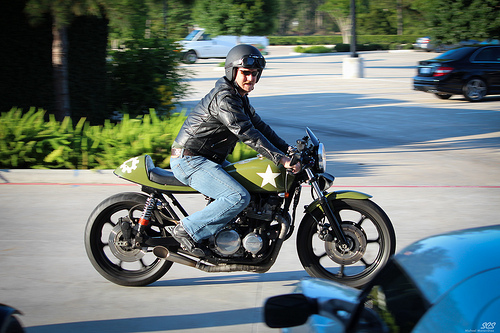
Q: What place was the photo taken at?
A: It was taken at the parking lot.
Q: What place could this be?
A: It is a parking lot.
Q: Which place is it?
A: It is a parking lot.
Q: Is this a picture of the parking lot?
A: Yes, it is showing the parking lot.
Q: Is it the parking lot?
A: Yes, it is the parking lot.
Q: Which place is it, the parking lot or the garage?
A: It is the parking lot.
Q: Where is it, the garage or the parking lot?
A: It is the parking lot.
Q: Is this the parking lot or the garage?
A: It is the parking lot.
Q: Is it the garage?
A: No, it is the parking lot.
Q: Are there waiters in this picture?
A: No, there are no waiters.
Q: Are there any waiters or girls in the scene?
A: No, there are no waiters or girls.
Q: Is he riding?
A: Yes, the man is riding.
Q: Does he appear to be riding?
A: Yes, the man is riding.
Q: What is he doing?
A: The man is riding.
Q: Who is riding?
A: The man is riding.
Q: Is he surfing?
A: No, the man is riding.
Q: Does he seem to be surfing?
A: No, the man is riding.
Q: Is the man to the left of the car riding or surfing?
A: The man is riding.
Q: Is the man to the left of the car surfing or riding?
A: The man is riding.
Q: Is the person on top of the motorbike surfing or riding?
A: The man is riding.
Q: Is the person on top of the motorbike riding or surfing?
A: The man is riding.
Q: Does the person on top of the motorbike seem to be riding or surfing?
A: The man is riding.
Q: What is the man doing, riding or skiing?
A: The man is riding.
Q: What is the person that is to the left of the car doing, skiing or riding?
A: The man is riding.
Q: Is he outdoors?
A: Yes, the man is outdoors.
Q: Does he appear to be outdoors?
A: Yes, the man is outdoors.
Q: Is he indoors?
A: No, the man is outdoors.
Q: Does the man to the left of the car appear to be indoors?
A: No, the man is outdoors.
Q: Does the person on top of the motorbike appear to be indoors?
A: No, the man is outdoors.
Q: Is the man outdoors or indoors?
A: The man is outdoors.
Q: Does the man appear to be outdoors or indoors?
A: The man is outdoors.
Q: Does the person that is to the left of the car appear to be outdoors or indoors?
A: The man is outdoors.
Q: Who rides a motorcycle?
A: The man rides a motorcycle.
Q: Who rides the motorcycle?
A: The man rides a motorcycle.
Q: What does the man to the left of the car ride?
A: The man rides a motorcycle.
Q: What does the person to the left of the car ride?
A: The man rides a motorcycle.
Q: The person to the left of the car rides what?
A: The man rides a motorcycle.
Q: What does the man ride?
A: The man rides a motorcycle.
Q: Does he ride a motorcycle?
A: Yes, the man rides a motorcycle.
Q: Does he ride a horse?
A: No, the man rides a motorcycle.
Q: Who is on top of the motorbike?
A: The man is on top of the motorbike.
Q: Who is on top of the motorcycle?
A: The man is on top of the motorbike.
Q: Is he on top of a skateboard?
A: No, the man is on top of the motorcycle.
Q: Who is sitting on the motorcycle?
A: The man is sitting on the motorcycle.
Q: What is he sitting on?
A: The man is sitting on the motorbike.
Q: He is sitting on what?
A: The man is sitting on the motorbike.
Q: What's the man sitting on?
A: The man is sitting on the motorbike.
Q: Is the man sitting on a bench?
A: No, the man is sitting on the motorbike.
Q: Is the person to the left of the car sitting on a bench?
A: No, the man is sitting on the motorbike.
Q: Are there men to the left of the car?
A: Yes, there is a man to the left of the car.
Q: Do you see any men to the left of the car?
A: Yes, there is a man to the left of the car.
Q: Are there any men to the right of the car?
A: No, the man is to the left of the car.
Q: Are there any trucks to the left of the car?
A: No, there is a man to the left of the car.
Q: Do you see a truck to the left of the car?
A: No, there is a man to the left of the car.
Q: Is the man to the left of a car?
A: Yes, the man is to the left of a car.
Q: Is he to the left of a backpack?
A: No, the man is to the left of a car.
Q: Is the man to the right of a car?
A: No, the man is to the left of a car.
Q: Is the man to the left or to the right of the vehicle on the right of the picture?
A: The man is to the left of the car.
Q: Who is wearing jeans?
A: The man is wearing jeans.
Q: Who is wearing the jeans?
A: The man is wearing jeans.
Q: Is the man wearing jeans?
A: Yes, the man is wearing jeans.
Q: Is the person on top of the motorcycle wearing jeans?
A: Yes, the man is wearing jeans.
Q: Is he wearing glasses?
A: No, the man is wearing jeans.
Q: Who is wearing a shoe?
A: The man is wearing a shoe.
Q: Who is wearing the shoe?
A: The man is wearing a shoe.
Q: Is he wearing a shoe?
A: Yes, the man is wearing a shoe.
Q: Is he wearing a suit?
A: No, the man is wearing a shoe.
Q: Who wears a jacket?
A: The man wears a jacket.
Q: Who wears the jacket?
A: The man wears a jacket.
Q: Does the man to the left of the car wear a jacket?
A: Yes, the man wears a jacket.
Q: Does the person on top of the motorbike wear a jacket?
A: Yes, the man wears a jacket.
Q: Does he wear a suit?
A: No, the man wears a jacket.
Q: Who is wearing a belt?
A: The man is wearing a belt.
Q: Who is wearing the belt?
A: The man is wearing a belt.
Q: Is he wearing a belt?
A: Yes, the man is wearing a belt.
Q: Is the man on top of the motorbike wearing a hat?
A: No, the man is wearing a belt.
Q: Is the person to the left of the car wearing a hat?
A: No, the man is wearing a belt.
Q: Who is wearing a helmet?
A: The man is wearing a helmet.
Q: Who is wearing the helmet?
A: The man is wearing a helmet.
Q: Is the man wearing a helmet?
A: Yes, the man is wearing a helmet.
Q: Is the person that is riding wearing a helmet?
A: Yes, the man is wearing a helmet.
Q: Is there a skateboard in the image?
A: No, there are no skateboards.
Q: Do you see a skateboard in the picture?
A: No, there are no skateboards.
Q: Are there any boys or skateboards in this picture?
A: No, there are no skateboards or boys.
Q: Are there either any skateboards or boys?
A: No, there are no skateboards or boys.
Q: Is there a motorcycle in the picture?
A: Yes, there is a motorcycle.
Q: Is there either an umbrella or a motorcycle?
A: Yes, there is a motorcycle.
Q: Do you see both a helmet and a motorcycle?
A: Yes, there are both a motorcycle and a helmet.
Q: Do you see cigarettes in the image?
A: No, there are no cigarettes.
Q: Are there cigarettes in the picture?
A: No, there are no cigarettes.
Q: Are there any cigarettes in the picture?
A: No, there are no cigarettes.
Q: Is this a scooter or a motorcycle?
A: This is a motorcycle.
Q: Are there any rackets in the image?
A: No, there are no rackets.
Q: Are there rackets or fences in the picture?
A: No, there are no rackets or fences.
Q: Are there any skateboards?
A: No, there are no skateboards.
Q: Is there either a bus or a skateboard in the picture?
A: No, there are no skateboards or buses.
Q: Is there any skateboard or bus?
A: No, there are no skateboards or buses.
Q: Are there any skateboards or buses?
A: No, there are no skateboards or buses.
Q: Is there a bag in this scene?
A: No, there are no bags.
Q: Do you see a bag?
A: No, there are no bags.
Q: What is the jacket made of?
A: The jacket is made of leather.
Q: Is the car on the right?
A: Yes, the car is on the right of the image.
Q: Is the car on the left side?
A: No, the car is on the right of the image.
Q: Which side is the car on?
A: The car is on the right of the image.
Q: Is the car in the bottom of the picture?
A: No, the car is in the top of the image.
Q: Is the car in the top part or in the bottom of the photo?
A: The car is in the top of the image.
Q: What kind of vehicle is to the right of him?
A: The vehicle is a car.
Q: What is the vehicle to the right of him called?
A: The vehicle is a car.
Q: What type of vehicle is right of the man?
A: The vehicle is a car.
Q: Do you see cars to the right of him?
A: Yes, there is a car to the right of the man.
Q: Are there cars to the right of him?
A: Yes, there is a car to the right of the man.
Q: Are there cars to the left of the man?
A: No, the car is to the right of the man.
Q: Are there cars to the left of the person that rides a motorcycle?
A: No, the car is to the right of the man.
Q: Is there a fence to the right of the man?
A: No, there is a car to the right of the man.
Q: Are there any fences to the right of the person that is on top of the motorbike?
A: No, there is a car to the right of the man.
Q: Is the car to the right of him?
A: Yes, the car is to the right of a man.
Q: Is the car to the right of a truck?
A: No, the car is to the right of a man.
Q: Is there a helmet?
A: Yes, there is a helmet.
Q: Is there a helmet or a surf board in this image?
A: Yes, there is a helmet.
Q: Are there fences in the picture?
A: No, there are no fences.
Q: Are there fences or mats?
A: No, there are no fences or mats.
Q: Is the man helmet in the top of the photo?
A: Yes, the helmet is in the top of the image.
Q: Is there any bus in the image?
A: No, there are no buses.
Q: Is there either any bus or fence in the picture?
A: No, there are no buses or fences.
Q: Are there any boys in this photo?
A: No, there are no boys.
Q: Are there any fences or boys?
A: No, there are no boys or fences.